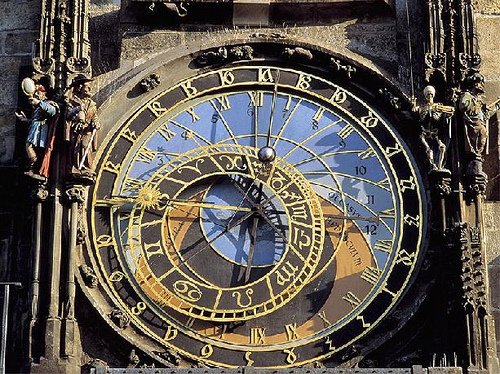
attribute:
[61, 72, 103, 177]
sculpture — on the side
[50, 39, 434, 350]
clock — yellow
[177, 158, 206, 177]
aries sign — astrological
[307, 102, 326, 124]
roman numeral — yellow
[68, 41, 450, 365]
clock — astronomical, yellow, medieval, weird, blue, brown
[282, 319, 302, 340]
numeral — yellow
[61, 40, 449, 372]
numbers — gold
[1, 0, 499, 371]
wall — gray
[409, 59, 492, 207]
skeleton — carved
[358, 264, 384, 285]
numeral — yellow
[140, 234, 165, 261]
gemini — astrological sign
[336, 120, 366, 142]
number — II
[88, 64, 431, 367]
clock — astronomical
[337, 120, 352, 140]
numeral — yellow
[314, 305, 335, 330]
x — number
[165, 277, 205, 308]
sign — cancer, astrological